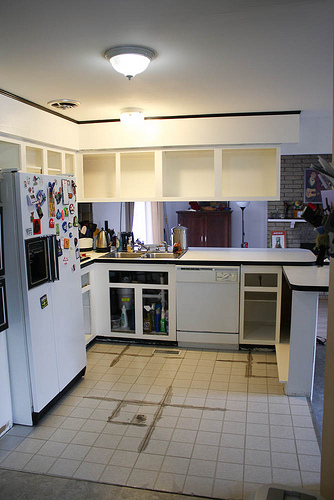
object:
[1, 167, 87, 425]
fridge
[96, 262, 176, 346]
cabinet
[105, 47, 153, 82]
lamp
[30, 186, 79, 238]
magnets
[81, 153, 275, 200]
cabinet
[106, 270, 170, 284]
drawers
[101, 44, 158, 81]
fixture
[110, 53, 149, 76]
bulb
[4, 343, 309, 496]
floor tiles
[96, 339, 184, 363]
repaired grout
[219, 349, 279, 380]
repaired grout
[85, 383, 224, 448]
repaired grout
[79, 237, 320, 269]
countertop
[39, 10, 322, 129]
ceiling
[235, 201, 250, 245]
floor lamp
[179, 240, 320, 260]
counter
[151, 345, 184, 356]
vent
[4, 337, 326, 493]
floor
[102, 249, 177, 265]
double sink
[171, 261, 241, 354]
dishwasher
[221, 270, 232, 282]
knob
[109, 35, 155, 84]
ceiling light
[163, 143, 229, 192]
square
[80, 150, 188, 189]
square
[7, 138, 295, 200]
shelves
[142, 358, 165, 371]
tile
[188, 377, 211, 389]
tile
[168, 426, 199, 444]
tile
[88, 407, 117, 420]
tile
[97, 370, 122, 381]
tile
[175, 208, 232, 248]
cabinet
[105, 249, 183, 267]
kitchen sink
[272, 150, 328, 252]
wall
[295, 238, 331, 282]
fireplace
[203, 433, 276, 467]
tiles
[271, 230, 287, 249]
artwork poster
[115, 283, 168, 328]
cleaning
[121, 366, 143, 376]
tile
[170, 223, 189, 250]
canister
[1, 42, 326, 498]
kitchen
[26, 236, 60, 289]
drink station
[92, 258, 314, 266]
side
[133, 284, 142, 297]
handles